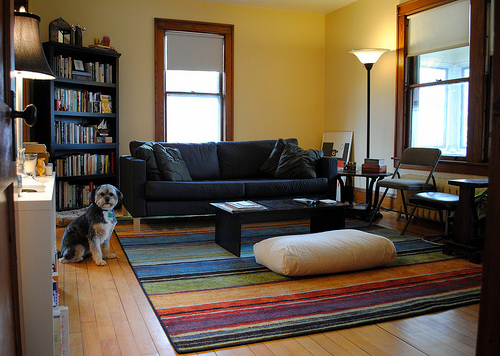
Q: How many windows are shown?
A: 2.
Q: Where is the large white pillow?
A: On the rug.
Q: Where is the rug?
A: On the floor.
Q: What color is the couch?
A: Black.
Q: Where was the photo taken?
A: Living room.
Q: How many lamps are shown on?
A: 2.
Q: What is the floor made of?
A: Wood.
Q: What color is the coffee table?
A: Black.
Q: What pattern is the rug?
A: Stripes.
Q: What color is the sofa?
A: Blue.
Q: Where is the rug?
A: On the floor.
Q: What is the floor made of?
A: Wood.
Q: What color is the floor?
A: Brown.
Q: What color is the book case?
A: Black.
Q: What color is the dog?
A: Gray and white.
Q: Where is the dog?
A: Next to the rug.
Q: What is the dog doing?
A: Sitting.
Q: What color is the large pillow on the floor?
A: White.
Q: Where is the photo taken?
A: Living room.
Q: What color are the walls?
A: Yellow.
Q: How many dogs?
A: 1.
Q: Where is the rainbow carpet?
A: On the ground.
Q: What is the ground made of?
A: Wood.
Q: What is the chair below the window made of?
A: Metal.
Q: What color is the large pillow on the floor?
A: White.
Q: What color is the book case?
A: Black.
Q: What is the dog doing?
A: Sitting.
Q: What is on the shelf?
A: Books.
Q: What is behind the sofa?
A: Window.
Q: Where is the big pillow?
A: Floor.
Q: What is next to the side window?
A: Lamp.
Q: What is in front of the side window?
A: Chair.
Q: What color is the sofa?
A: Black.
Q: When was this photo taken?
A: Daytime.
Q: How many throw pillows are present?
A: 4.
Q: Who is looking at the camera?
A: Dog.